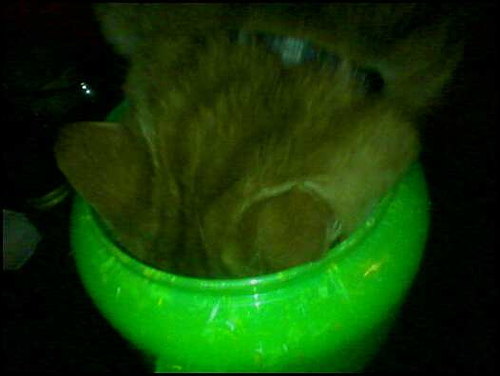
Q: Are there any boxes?
A: No, there are no boxes.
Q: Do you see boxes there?
A: No, there are no boxes.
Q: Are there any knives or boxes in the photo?
A: No, there are no boxes or knives.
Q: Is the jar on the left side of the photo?
A: Yes, the jar is on the left of the image.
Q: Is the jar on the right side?
A: No, the jar is on the left of the image.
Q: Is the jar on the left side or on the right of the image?
A: The jar is on the left of the image.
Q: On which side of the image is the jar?
A: The jar is on the left of the image.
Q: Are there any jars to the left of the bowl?
A: Yes, there is a jar to the left of the bowl.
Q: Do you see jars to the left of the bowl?
A: Yes, there is a jar to the left of the bowl.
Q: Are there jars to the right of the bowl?
A: No, the jar is to the left of the bowl.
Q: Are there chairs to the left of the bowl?
A: No, there is a jar to the left of the bowl.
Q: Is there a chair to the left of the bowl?
A: No, there is a jar to the left of the bowl.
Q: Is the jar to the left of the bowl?
A: Yes, the jar is to the left of the bowl.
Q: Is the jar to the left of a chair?
A: No, the jar is to the left of the bowl.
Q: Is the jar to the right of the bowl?
A: No, the jar is to the left of the bowl.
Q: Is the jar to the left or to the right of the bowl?
A: The jar is to the left of the bowl.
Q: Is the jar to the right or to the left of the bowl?
A: The jar is to the left of the bowl.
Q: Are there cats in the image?
A: Yes, there is a cat.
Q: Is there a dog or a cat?
A: Yes, there is a cat.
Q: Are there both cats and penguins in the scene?
A: No, there is a cat but no penguins.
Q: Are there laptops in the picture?
A: No, there are no laptops.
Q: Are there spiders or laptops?
A: No, there are no laptops or spiders.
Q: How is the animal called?
A: The animal is a cat.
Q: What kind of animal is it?
A: The animal is a cat.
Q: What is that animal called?
A: This is a cat.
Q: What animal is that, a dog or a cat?
A: This is a cat.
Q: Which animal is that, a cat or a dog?
A: This is a cat.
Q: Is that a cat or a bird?
A: That is a cat.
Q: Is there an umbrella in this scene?
A: No, there are no umbrellas.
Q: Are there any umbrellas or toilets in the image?
A: No, there are no umbrellas or toilets.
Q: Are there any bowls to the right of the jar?
A: Yes, there is a bowl to the right of the jar.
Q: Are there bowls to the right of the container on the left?
A: Yes, there is a bowl to the right of the jar.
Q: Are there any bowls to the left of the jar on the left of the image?
A: No, the bowl is to the right of the jar.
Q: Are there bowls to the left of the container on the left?
A: No, the bowl is to the right of the jar.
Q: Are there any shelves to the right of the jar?
A: No, there is a bowl to the right of the jar.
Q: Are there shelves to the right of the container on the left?
A: No, there is a bowl to the right of the jar.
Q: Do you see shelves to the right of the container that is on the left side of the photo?
A: No, there is a bowl to the right of the jar.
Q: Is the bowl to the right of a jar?
A: Yes, the bowl is to the right of a jar.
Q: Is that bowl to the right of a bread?
A: No, the bowl is to the right of a jar.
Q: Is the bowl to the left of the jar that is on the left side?
A: No, the bowl is to the right of the jar.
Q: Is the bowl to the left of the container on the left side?
A: No, the bowl is to the right of the jar.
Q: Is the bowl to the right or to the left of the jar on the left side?
A: The bowl is to the right of the jar.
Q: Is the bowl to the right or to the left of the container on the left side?
A: The bowl is to the right of the jar.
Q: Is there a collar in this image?
A: Yes, there is a collar.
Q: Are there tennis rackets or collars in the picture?
A: Yes, there is a collar.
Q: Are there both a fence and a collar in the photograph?
A: No, there is a collar but no fences.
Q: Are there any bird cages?
A: No, there are no bird cages.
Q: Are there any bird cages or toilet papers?
A: No, there are no bird cages or toilet papers.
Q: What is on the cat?
A: The collar is on the cat.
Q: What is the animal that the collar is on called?
A: The animal is a cat.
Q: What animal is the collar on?
A: The collar is on the cat.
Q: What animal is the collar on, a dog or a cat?
A: The collar is on a cat.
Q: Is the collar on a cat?
A: Yes, the collar is on a cat.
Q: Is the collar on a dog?
A: No, the collar is on a cat.